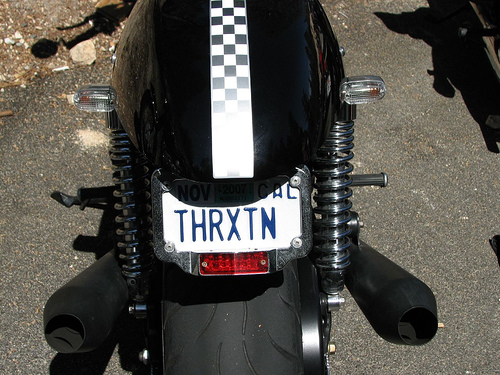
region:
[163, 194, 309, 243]
License plate on the motorcycle.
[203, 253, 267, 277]
Red light on the back of the motorcycle.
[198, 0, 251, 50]
Black checkered marks on the motorcycle.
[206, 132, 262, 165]
White on the motorcycle.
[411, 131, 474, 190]
The ground is paved.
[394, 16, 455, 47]
Shadow is being cast.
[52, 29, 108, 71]
Large rock on the side of the road.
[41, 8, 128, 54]
The handle bar is black.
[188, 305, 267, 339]
Grooves on the tire.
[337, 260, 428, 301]
Black pipe on the motorcycle.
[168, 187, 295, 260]
The plate is white and blue.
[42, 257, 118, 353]
The muffler is black.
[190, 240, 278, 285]
The taillight is red.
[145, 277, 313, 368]
The back tire is on the motorcycle.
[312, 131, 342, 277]
Silver springs on the side of bike.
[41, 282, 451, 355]
The bike has two mufflers.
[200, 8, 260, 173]
A long black and white line on the seat.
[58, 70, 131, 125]
Two small lights on the motorcycle.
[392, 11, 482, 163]
A shadow on the ground.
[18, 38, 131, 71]
A white rock is on the ground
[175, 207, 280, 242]
capital letters on the license plate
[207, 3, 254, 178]
checkerboard design on back of motorcycle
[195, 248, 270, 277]
back break light of motorcycle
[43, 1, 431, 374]
motorcycle viewed from the back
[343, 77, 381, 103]
back right blinker light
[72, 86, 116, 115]
back left blinker light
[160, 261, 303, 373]
back tire of motorcycle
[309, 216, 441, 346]
back right exhaust of motorcycle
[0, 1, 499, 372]
pavement motorcycle is parked in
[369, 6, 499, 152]
shadow of another vehicle to the right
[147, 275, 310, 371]
worn tire of a bike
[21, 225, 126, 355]
exhaust pipe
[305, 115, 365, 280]
a shock absorber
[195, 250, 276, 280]
red reflector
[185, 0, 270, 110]
black and white checkered pattern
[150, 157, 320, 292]
motorcycle license plate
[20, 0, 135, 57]
shadow of a bike handle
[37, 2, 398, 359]
motorcycle set on a road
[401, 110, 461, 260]
black pavement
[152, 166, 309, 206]
identification of month and state of plate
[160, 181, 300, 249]
A white license plate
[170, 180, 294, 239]
Blue letters on a license plate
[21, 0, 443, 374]
The back of a motorcycle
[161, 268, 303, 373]
Motorcycle tire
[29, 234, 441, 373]
two black exhaust pipes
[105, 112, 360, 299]
Two suspension coils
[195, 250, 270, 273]
A red brake light under the license plate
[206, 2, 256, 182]
A white and black checkered stripe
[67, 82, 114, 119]
Left turn signal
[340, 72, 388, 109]
Right turn signal